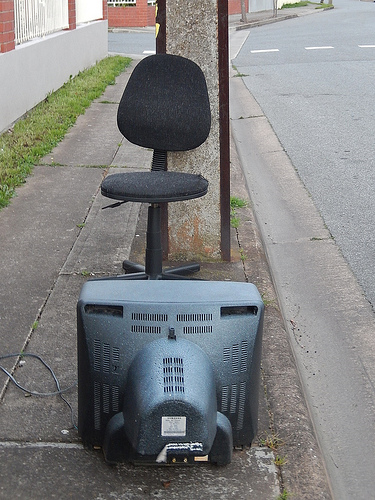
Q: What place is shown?
A: It is a road.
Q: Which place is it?
A: It is a road.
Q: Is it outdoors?
A: Yes, it is outdoors.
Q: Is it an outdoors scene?
A: Yes, it is outdoors.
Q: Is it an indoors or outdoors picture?
A: It is outdoors.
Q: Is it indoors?
A: No, it is outdoors.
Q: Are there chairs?
A: Yes, there is a chair.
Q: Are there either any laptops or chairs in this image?
A: Yes, there is a chair.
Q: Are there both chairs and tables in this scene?
A: No, there is a chair but no tables.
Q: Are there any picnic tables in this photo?
A: No, there are no picnic tables.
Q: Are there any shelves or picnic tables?
A: No, there are no picnic tables or shelves.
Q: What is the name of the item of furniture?
A: The piece of furniture is a chair.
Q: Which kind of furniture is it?
A: The piece of furniture is a chair.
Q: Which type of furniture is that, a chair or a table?
A: That is a chair.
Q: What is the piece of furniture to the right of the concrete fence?
A: The piece of furniture is a chair.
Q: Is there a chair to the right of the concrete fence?
A: Yes, there is a chair to the right of the fence.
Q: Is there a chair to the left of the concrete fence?
A: No, the chair is to the right of the fence.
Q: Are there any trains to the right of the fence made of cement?
A: No, there is a chair to the right of the fence.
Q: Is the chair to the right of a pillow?
A: No, the chair is to the right of a fence.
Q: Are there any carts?
A: No, there are no carts.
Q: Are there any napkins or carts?
A: No, there are no carts or napkins.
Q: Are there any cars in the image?
A: No, there are no cars.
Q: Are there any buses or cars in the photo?
A: No, there are no cars or buses.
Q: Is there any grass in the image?
A: Yes, there is grass.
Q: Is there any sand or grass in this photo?
A: Yes, there is grass.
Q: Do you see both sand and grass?
A: No, there is grass but no sand.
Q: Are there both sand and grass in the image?
A: No, there is grass but no sand.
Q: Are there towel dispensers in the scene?
A: No, there are no towel dispensers.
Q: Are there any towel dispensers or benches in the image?
A: No, there are no towel dispensers or benches.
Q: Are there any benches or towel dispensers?
A: No, there are no towel dispensers or benches.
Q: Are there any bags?
A: No, there are no bags.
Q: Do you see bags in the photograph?
A: No, there are no bags.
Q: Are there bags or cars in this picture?
A: No, there are no bags or cars.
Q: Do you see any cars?
A: No, there are no cars.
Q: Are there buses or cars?
A: No, there are no cars or buses.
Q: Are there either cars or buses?
A: No, there are no cars or buses.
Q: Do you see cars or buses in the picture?
A: No, there are no cars or buses.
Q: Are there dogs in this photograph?
A: No, there are no dogs.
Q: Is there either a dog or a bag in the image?
A: No, there are no dogs or bags.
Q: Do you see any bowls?
A: No, there are no bowls.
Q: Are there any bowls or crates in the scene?
A: No, there are no bowls or crates.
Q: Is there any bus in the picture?
A: No, there are no buses.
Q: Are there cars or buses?
A: No, there are no buses or cars.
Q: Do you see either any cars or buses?
A: No, there are no buses or cars.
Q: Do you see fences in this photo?
A: Yes, there is a fence.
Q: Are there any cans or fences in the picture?
A: Yes, there is a fence.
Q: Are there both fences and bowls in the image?
A: No, there is a fence but no bowls.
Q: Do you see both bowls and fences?
A: No, there is a fence but no bowls.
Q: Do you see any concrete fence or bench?
A: Yes, there is a concrete fence.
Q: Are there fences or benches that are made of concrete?
A: Yes, the fence is made of concrete.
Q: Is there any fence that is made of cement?
A: Yes, there is a fence that is made of cement.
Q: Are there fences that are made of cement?
A: Yes, there is a fence that is made of cement.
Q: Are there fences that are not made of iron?
A: Yes, there is a fence that is made of cement.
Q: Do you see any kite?
A: No, there are no kites.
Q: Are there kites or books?
A: No, there are no kites or books.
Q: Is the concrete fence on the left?
A: Yes, the fence is on the left of the image.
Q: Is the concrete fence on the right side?
A: No, the fence is on the left of the image.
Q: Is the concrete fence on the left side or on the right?
A: The fence is on the left of the image.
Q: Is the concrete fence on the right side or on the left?
A: The fence is on the left of the image.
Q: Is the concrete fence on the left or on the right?
A: The fence is on the left of the image.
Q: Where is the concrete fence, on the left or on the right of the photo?
A: The fence is on the left of the image.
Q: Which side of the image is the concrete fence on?
A: The fence is on the left of the image.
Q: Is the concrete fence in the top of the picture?
A: Yes, the fence is in the top of the image.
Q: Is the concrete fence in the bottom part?
A: No, the fence is in the top of the image.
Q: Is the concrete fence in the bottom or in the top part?
A: The fence is in the top of the image.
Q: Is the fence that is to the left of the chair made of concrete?
A: Yes, the fence is made of concrete.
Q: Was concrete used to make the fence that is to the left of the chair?
A: Yes, the fence is made of concrete.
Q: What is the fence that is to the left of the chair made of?
A: The fence is made of cement.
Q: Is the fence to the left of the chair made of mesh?
A: No, the fence is made of cement.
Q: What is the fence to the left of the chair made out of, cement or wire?
A: The fence is made of cement.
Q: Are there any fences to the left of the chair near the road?
A: Yes, there is a fence to the left of the chair.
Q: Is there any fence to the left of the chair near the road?
A: Yes, there is a fence to the left of the chair.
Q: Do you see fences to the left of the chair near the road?
A: Yes, there is a fence to the left of the chair.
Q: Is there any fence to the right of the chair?
A: No, the fence is to the left of the chair.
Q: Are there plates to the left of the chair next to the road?
A: No, there is a fence to the left of the chair.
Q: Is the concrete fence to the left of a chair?
A: Yes, the fence is to the left of a chair.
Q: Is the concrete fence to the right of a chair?
A: No, the fence is to the left of a chair.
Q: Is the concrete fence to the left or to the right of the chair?
A: The fence is to the left of the chair.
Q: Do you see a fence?
A: Yes, there is a fence.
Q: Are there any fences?
A: Yes, there is a fence.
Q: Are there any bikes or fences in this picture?
A: Yes, there is a fence.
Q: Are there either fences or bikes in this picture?
A: Yes, there is a fence.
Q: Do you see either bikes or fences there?
A: Yes, there is a fence.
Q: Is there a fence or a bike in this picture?
A: Yes, there is a fence.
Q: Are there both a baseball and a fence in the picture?
A: No, there is a fence but no baseballs.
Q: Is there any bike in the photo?
A: No, there are no bikes.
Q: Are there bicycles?
A: No, there are no bicycles.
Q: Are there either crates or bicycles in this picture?
A: No, there are no bicycles or crates.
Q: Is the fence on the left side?
A: Yes, the fence is on the left of the image.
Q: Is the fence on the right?
A: No, the fence is on the left of the image.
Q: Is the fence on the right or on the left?
A: The fence is on the left of the image.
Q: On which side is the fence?
A: The fence is on the left of the image.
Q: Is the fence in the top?
A: Yes, the fence is in the top of the image.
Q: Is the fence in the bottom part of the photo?
A: No, the fence is in the top of the image.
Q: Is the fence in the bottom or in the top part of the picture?
A: The fence is in the top of the image.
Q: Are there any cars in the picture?
A: No, there are no cars.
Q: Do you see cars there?
A: No, there are no cars.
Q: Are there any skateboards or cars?
A: No, there are no cars or skateboards.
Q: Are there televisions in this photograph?
A: Yes, there is a television.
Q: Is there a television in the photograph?
A: Yes, there is a television.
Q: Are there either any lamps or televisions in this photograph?
A: Yes, there is a television.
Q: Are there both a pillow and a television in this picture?
A: No, there is a television but no pillows.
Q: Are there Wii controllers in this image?
A: No, there are no Wii controllers.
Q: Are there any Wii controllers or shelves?
A: No, there are no Wii controllers or shelves.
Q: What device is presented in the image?
A: The device is a television.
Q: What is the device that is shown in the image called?
A: The device is a television.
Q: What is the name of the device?
A: The device is a television.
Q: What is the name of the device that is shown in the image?
A: The device is a television.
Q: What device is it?
A: The device is a television.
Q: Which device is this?
A: This is a television.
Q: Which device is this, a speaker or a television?
A: This is a television.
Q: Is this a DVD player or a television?
A: This is a television.